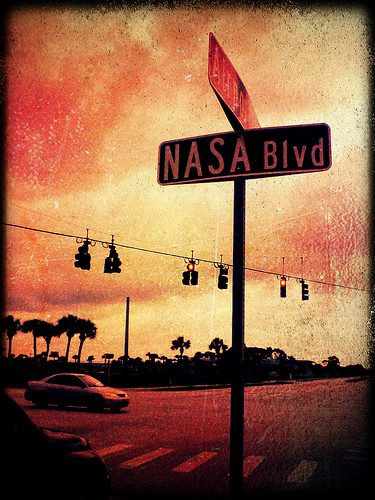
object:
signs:
[208, 29, 261, 131]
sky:
[23, 143, 171, 230]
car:
[24, 373, 130, 414]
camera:
[36, 424, 109, 490]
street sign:
[153, 120, 333, 188]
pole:
[229, 181, 245, 497]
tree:
[74, 316, 97, 365]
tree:
[53, 314, 79, 361]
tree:
[34, 321, 55, 363]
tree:
[19, 318, 40, 357]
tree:
[0, 313, 21, 360]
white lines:
[74, 436, 319, 483]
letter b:
[263, 141, 277, 170]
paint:
[83, 429, 335, 485]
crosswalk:
[64, 432, 374, 491]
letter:
[311, 138, 325, 167]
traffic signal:
[103, 247, 121, 273]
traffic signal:
[217, 266, 229, 289]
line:
[3, 222, 231, 266]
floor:
[258, 382, 366, 437]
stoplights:
[300, 279, 310, 302]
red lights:
[279, 279, 286, 287]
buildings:
[246, 345, 370, 383]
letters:
[164, 144, 180, 180]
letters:
[184, 141, 203, 178]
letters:
[208, 137, 224, 175]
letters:
[229, 135, 251, 172]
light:
[280, 278, 287, 298]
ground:
[6, 378, 371, 497]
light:
[188, 263, 194, 271]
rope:
[3, 223, 368, 299]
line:
[94, 442, 133, 458]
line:
[120, 446, 174, 468]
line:
[173, 450, 216, 473]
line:
[228, 454, 264, 480]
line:
[288, 457, 318, 486]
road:
[13, 378, 371, 497]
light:
[182, 260, 199, 286]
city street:
[5, 360, 373, 500]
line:
[244, 266, 370, 296]